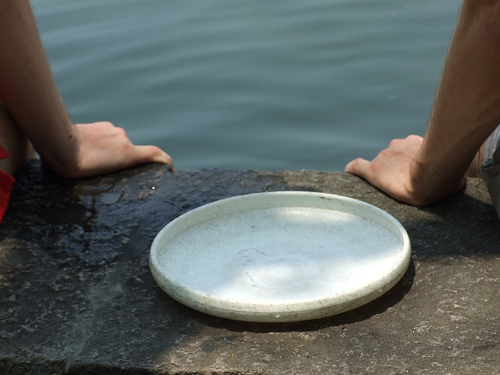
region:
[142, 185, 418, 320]
white frisbee in between two people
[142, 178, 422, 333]
upside down frisbee on frisbeee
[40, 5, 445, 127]
body of water in front of people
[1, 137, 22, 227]
small piece of red shorts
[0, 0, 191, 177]
arm resting on concrete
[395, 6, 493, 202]
man resting arm on concrete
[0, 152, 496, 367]
concrete holding frisbee and two people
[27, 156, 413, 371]
frisbee on top of concrete concrete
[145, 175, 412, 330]
frisbee in front of water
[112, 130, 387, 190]
concrete that is separating hands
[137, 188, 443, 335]
white Frisbee on a rock.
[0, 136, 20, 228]
red swimming shorts.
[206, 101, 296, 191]
rock bench near water.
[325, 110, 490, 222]
left hand on a rock bench.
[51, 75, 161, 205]
right hand on a wet rock bench.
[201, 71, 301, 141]
calm water without waves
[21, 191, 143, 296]
wet rock bench being sat on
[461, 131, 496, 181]
grey swimming trunks on a person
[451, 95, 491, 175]
veins in an arm.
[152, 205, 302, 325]
white Frisbee on a rock.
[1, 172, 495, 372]
concrete ledge on the waterfront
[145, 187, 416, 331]
an upside down white flying disc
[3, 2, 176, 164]
an arm and hand on the edge of the water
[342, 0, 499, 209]
an arm and hand on the edge of the water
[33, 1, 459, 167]
dark murky lake water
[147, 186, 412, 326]
a white frisbee sitting on a ledge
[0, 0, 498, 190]
two people sitting on the side of a lake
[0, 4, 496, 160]
dark rippling lake water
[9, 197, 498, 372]
a shadow of the person on the left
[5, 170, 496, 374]
stone dock with a white flying disk on it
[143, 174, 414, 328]
a white upside down frisbee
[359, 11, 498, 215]
a person sitting on a stone wall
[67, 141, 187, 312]
a stone wall that is wet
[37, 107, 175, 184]
a person's hand leaning on rock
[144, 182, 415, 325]
a worn out frisbee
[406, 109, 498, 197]
veins raising the skins surface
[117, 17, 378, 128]
small disturbances on the water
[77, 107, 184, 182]
the pinky finger is extended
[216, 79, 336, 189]
wet stone and dry stone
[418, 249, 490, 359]
rough stone surface